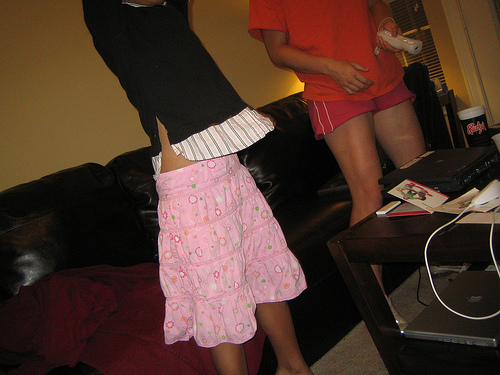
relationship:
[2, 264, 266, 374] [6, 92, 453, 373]
fabric on couch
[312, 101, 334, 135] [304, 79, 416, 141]
stripes on shorts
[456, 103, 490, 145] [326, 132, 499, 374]
cup on table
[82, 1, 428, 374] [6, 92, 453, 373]
people in front of couch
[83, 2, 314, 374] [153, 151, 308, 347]
girl wearing a skirt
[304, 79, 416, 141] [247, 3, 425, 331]
shorts on a girl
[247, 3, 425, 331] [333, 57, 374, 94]
girl has a right hand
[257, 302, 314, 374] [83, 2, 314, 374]
left leg on girl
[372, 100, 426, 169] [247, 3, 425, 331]
left leg on girl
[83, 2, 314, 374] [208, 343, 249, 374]
girl has a right leg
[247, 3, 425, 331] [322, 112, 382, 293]
girl has a right leg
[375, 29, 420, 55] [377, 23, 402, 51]
controller in left hand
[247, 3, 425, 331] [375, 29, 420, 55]
girl holding controller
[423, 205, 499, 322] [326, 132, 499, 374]
cord on table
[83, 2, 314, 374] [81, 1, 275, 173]
girl wearing a top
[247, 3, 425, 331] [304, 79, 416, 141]
girl wearing shorts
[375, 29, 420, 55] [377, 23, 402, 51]
controller in lef hand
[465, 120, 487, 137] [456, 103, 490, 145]
writing on a cup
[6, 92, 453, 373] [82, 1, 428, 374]
couch behind people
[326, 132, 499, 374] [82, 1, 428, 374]
table in front of people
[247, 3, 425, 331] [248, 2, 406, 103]
girl wearing a shirt